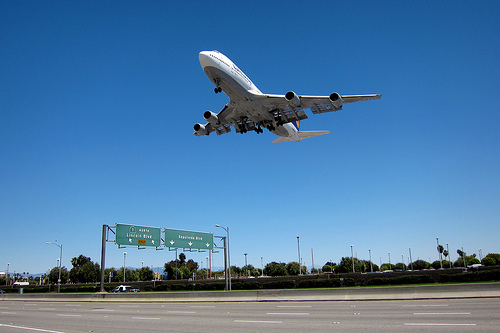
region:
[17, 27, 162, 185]
The sky is clear.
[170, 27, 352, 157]
The plane is taking off.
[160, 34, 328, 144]
The plane is white.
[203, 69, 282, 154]
The wheels are down.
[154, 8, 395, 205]
The plane is small.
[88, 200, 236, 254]
The signs are green.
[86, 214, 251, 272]
The signs have white lettering.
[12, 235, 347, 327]
The street is clear.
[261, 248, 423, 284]
The bushes are green.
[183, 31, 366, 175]
The plane has jets.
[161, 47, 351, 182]
commercial airplane flying above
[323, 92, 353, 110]
engine on side of plane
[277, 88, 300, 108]
engine on side of plane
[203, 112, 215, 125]
engine on side of plane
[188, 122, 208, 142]
engine on side of plane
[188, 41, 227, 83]
nose of large plane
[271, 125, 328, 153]
back tail of plane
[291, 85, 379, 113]
side wing of plane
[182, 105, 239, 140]
side wing of plane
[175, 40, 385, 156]
Underside of a commercial airplane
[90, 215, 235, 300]
Street signs giving directions at an airport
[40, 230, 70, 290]
Street light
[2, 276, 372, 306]
Concrete divider providing a barrier between lanes going in different directions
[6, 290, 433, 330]
Four lanes for cars traveling to the right on this road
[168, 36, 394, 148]
Airplane that has just taken off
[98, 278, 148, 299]
A car on the highway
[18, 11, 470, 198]
White airplane in a clear blue sky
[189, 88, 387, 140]
Four plane engines, two on each wing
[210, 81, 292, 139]
Landing gear extended on an airplane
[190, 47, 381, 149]
airplane flying in sky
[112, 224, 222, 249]
two green signboards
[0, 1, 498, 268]
blue clear sky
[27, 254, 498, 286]
small trees at bottom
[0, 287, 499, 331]
gray pavement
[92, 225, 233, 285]
two gray poles where signboards are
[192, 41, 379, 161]
airplane blast off airport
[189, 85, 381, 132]
two small wings of airplane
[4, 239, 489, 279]
bunch of white poles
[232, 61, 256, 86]
bunch of windows in the airplane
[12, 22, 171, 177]
the clear blue sky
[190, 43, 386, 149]
the airplane on the sky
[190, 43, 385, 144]
the big airplane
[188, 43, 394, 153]
the airplane in the mid air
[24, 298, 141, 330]
the gray paved road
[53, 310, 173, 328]
the dashed white lines on the road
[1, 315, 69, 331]
the solid white line on the road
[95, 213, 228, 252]
the big green signs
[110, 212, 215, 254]
the big green highway signs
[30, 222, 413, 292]
the street lights